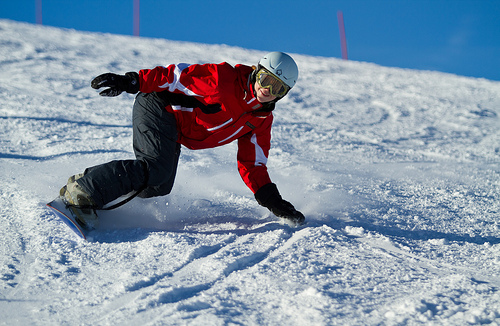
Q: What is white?
A: Snow.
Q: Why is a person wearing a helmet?
A: Person is snowboarding.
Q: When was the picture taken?
A: Daytime.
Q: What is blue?
A: Sky.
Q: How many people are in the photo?
A: One.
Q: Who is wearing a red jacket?
A: Snowboarder.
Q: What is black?
A: Gloves.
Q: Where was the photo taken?
A: On a snow covered mountain.